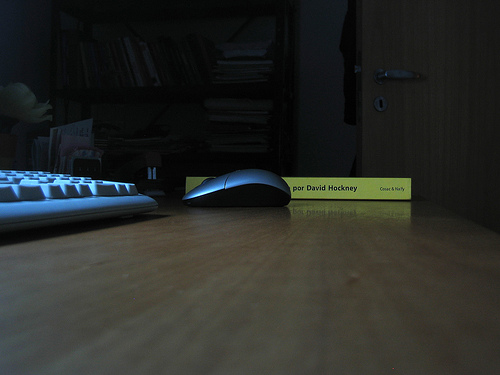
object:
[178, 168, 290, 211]
mouse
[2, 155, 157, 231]
computer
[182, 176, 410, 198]
book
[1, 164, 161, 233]
key pad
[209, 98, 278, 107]
books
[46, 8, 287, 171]
shelf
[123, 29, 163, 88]
documents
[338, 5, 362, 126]
jacket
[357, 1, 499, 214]
door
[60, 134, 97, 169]
mail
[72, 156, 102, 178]
holder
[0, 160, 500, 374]
desk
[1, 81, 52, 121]
flower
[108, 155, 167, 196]
stapler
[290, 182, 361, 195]
david hockney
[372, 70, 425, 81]
handle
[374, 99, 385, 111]
keyhole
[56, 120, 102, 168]
papers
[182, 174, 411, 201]
spine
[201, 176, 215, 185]
clicker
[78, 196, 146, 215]
edge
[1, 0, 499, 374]
room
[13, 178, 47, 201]
keys